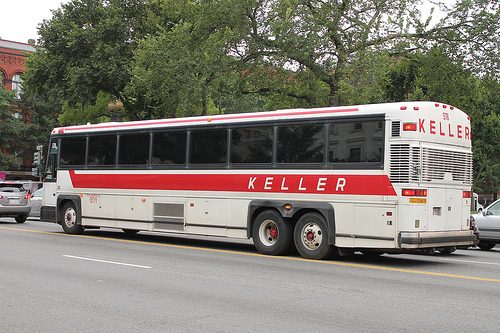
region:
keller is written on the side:
[243, 168, 373, 205]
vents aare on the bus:
[398, 143, 470, 197]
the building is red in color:
[3, 50, 25, 67]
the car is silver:
[1, 183, 41, 217]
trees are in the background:
[106, 58, 449, 98]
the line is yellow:
[349, 258, 479, 292]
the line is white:
[60, 247, 156, 274]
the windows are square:
[70, 118, 372, 169]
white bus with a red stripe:
[34, 83, 486, 247]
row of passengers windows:
[59, 114, 384, 184]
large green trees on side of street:
[43, 4, 470, 133]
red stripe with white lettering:
[64, 165, 400, 210]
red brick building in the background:
[5, 18, 55, 124]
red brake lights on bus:
[400, 180, 480, 200]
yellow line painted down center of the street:
[16, 210, 491, 306]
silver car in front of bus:
[2, 168, 33, 231]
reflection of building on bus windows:
[258, 115, 378, 165]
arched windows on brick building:
[4, 65, 33, 115]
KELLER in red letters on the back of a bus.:
[416, 117, 469, 139]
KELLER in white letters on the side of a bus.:
[247, 172, 345, 193]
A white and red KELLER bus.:
[41, 100, 475, 255]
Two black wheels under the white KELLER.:
[250, 208, 333, 261]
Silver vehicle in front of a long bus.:
[2, 181, 32, 223]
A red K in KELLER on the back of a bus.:
[417, 116, 425, 133]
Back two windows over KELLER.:
[276, 113, 387, 166]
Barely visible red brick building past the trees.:
[0, 35, 47, 120]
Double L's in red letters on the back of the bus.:
[438, 121, 454, 137]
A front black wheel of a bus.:
[57, 200, 82, 234]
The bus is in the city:
[10, 31, 490, 316]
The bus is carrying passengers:
[17, 45, 479, 300]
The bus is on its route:
[6, 61, 489, 316]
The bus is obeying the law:
[0, 40, 488, 316]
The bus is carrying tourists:
[21, 57, 497, 302]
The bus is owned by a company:
[15, 58, 496, 329]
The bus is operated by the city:
[21, 27, 487, 313]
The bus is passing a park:
[11, 60, 486, 325]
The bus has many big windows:
[1, 55, 476, 318]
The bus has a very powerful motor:
[32, 60, 491, 320]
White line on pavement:
[58, 249, 161, 299]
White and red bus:
[26, 109, 495, 276]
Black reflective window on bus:
[325, 112, 385, 172]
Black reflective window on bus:
[273, 118, 328, 176]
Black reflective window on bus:
[228, 118, 275, 173]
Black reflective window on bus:
[186, 124, 228, 176]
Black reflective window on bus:
[148, 123, 193, 186]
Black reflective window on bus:
[117, 126, 153, 173]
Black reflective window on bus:
[86, 126, 116, 170]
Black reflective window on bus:
[56, 128, 93, 178]